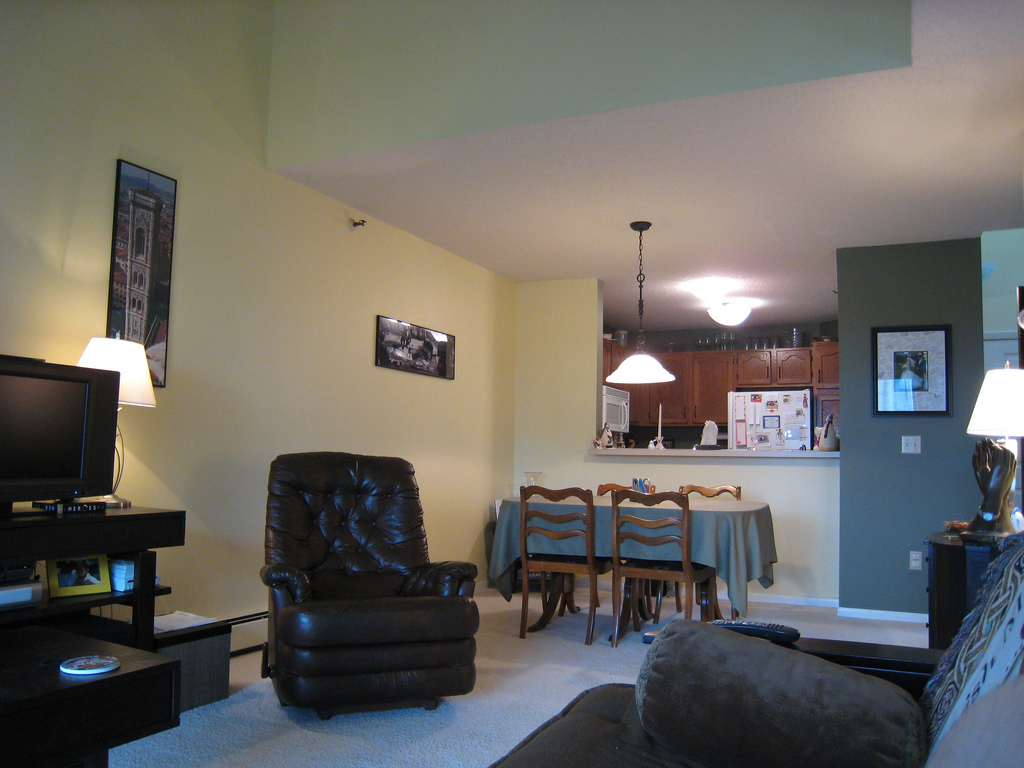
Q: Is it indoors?
A: Yes, it is indoors.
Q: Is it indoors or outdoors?
A: It is indoors.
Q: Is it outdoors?
A: No, it is indoors.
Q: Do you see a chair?
A: Yes, there is a chair.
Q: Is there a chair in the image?
A: Yes, there is a chair.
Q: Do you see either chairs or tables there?
A: Yes, there is a chair.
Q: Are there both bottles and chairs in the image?
A: No, there is a chair but no bottles.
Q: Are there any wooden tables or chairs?
A: Yes, there is a wood chair.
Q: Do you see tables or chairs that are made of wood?
A: Yes, the chair is made of wood.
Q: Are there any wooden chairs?
A: Yes, there is a wood chair.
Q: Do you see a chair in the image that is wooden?
A: Yes, there is a chair that is wooden.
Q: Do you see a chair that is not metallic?
A: Yes, there is a wooden chair.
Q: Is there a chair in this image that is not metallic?
A: Yes, there is a wooden chair.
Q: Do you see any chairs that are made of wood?
A: Yes, there is a chair that is made of wood.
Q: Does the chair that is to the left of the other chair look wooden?
A: Yes, the chair is wooden.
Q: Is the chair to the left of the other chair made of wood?
A: Yes, the chair is made of wood.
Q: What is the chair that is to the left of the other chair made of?
A: The chair is made of wood.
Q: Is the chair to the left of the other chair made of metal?
A: No, the chair is made of wood.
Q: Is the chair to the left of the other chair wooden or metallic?
A: The chair is wooden.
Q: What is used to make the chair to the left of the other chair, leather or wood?
A: The chair is made of wood.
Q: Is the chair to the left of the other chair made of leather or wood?
A: The chair is made of wood.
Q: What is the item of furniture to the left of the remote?
A: The piece of furniture is a chair.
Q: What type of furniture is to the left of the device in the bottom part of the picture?
A: The piece of furniture is a chair.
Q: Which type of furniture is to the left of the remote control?
A: The piece of furniture is a chair.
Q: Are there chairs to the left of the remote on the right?
A: Yes, there is a chair to the left of the remote.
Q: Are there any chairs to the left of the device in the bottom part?
A: Yes, there is a chair to the left of the remote.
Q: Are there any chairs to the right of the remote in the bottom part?
A: No, the chair is to the left of the remote.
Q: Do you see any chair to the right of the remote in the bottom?
A: No, the chair is to the left of the remote.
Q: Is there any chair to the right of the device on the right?
A: No, the chair is to the left of the remote.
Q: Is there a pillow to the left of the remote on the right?
A: No, there is a chair to the left of the remote control.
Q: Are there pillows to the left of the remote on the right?
A: No, there is a chair to the left of the remote control.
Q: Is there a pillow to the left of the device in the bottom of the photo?
A: No, there is a chair to the left of the remote control.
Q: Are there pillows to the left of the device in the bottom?
A: No, there is a chair to the left of the remote control.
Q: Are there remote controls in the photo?
A: Yes, there is a remote control.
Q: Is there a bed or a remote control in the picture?
A: Yes, there is a remote control.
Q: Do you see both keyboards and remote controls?
A: No, there is a remote control but no keyboards.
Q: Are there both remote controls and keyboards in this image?
A: No, there is a remote control but no keyboards.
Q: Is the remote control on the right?
A: Yes, the remote control is on the right of the image.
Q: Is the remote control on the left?
A: No, the remote control is on the right of the image.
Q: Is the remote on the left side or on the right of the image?
A: The remote is on the right of the image.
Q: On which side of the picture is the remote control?
A: The remote control is on the right of the image.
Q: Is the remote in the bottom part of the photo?
A: Yes, the remote is in the bottom of the image.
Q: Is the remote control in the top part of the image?
A: No, the remote control is in the bottom of the image.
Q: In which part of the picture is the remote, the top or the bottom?
A: The remote is in the bottom of the image.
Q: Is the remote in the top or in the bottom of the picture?
A: The remote is in the bottom of the image.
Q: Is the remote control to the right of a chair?
A: Yes, the remote control is to the right of a chair.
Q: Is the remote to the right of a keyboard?
A: No, the remote is to the right of a chair.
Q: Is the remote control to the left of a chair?
A: No, the remote control is to the right of a chair.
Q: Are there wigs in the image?
A: No, there are no wigs.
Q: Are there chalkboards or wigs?
A: No, there are no wigs or chalkboards.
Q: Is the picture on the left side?
A: Yes, the picture is on the left of the image.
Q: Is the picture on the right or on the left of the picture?
A: The picture is on the left of the image.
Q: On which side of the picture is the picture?
A: The picture is on the left of the image.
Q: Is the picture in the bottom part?
A: Yes, the picture is in the bottom of the image.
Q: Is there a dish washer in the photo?
A: No, there are no dishwashers.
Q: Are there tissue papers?
A: No, there are no tissue papers.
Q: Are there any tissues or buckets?
A: No, there are no tissues or buckets.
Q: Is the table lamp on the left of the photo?
A: Yes, the table lamp is on the left of the image.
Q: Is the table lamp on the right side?
A: No, the table lamp is on the left of the image.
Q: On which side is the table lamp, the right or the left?
A: The table lamp is on the left of the image.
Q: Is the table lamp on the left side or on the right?
A: The table lamp is on the left of the image.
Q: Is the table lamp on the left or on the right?
A: The table lamp is on the left of the image.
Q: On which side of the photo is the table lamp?
A: The table lamp is on the left of the image.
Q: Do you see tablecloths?
A: Yes, there is a tablecloth.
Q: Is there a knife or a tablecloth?
A: Yes, there is a tablecloth.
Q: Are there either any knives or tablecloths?
A: Yes, there is a tablecloth.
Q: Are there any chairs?
A: Yes, there is a chair.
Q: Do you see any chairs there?
A: Yes, there is a chair.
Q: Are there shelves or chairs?
A: Yes, there is a chair.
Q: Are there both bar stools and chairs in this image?
A: No, there is a chair but no bar stools.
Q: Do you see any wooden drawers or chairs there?
A: Yes, there is a wood chair.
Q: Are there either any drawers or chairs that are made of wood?
A: Yes, the chair is made of wood.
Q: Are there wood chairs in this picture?
A: Yes, there is a wood chair.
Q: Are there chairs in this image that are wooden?
A: Yes, there is a chair that is wooden.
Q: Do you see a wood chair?
A: Yes, there is a chair that is made of wood.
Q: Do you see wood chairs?
A: Yes, there is a chair that is made of wood.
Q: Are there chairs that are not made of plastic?
A: Yes, there is a chair that is made of wood.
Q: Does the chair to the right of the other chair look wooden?
A: Yes, the chair is wooden.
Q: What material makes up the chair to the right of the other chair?
A: The chair is made of wood.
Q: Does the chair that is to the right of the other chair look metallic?
A: No, the chair is wooden.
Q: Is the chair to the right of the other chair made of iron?
A: No, the chair is made of wood.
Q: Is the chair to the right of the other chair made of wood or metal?
A: The chair is made of wood.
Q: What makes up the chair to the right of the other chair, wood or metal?
A: The chair is made of wood.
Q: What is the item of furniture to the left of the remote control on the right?
A: The piece of furniture is a chair.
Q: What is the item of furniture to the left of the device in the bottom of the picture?
A: The piece of furniture is a chair.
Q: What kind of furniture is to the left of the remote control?
A: The piece of furniture is a chair.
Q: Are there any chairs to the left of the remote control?
A: Yes, there is a chair to the left of the remote control.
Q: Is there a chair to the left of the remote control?
A: Yes, there is a chair to the left of the remote control.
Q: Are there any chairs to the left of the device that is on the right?
A: Yes, there is a chair to the left of the remote control.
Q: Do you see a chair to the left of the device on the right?
A: Yes, there is a chair to the left of the remote control.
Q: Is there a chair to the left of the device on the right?
A: Yes, there is a chair to the left of the remote control.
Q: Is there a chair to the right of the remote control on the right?
A: No, the chair is to the left of the remote control.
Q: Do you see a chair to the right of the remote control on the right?
A: No, the chair is to the left of the remote control.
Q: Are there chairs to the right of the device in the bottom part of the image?
A: No, the chair is to the left of the remote control.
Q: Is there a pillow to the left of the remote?
A: No, there is a chair to the left of the remote.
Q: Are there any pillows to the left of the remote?
A: No, there is a chair to the left of the remote.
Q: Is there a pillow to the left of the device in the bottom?
A: No, there is a chair to the left of the remote.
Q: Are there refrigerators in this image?
A: Yes, there is a refrigerator.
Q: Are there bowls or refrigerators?
A: Yes, there is a refrigerator.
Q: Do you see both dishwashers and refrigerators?
A: No, there is a refrigerator but no dishwashers.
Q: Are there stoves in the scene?
A: No, there are no stoves.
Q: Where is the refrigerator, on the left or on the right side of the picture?
A: The refrigerator is on the right of the image.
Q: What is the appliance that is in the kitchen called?
A: The appliance is a refrigerator.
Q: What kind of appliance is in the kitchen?
A: The appliance is a refrigerator.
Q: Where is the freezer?
A: The freezer is in the kitchen.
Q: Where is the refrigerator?
A: The freezer is in the kitchen.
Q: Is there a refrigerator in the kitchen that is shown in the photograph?
A: Yes, there is a refrigerator in the kitchen.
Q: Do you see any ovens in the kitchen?
A: No, there is a refrigerator in the kitchen.